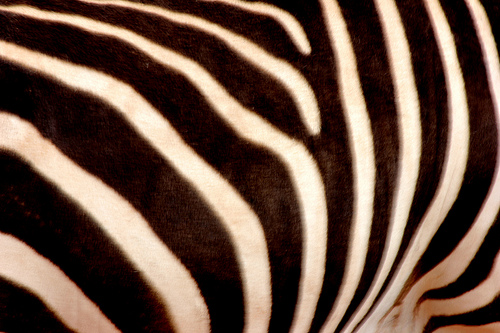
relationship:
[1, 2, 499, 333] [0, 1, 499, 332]
pattern visible on a zebra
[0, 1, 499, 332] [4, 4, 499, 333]
zebra has a side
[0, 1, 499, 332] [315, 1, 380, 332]
zebra has a white stripe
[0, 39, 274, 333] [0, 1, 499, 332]
stripe on a zebra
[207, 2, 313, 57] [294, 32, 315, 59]
stripe has an end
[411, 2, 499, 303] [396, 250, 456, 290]
stripe has an end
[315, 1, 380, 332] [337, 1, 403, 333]
white stripe next to black stripe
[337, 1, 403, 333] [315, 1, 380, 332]
black stripe next to white stripe